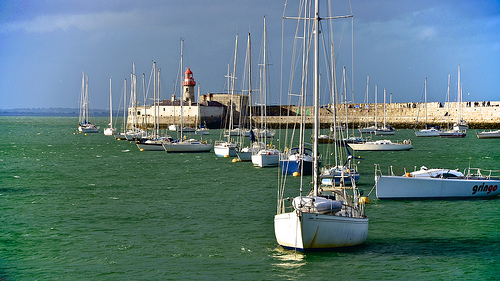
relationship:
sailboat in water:
[265, 2, 373, 246] [1, 115, 498, 280]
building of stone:
[151, 73, 247, 117] [132, 92, 245, 132]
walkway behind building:
[228, 96, 500, 127] [151, 73, 247, 117]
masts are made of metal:
[289, 1, 344, 199] [305, 2, 326, 203]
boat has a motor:
[349, 138, 413, 151] [403, 138, 411, 145]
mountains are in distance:
[2, 103, 136, 119] [4, 94, 130, 120]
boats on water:
[74, 69, 295, 182] [1, 115, 498, 280]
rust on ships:
[277, 237, 367, 249] [265, 2, 373, 246]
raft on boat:
[294, 194, 338, 215] [267, 5, 372, 243]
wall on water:
[241, 111, 500, 132] [1, 115, 498, 280]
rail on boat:
[277, 194, 306, 215] [267, 5, 372, 243]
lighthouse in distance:
[182, 68, 194, 85] [4, 94, 130, 120]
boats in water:
[74, 69, 295, 182] [1, 115, 498, 280]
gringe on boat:
[472, 182, 500, 196] [374, 162, 493, 197]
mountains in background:
[2, 103, 136, 119] [0, 14, 499, 139]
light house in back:
[179, 67, 203, 102] [134, 65, 495, 105]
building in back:
[151, 73, 247, 117] [134, 65, 495, 105]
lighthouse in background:
[182, 68, 194, 85] [0, 14, 499, 139]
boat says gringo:
[374, 162, 493, 197] [472, 182, 500, 196]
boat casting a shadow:
[267, 5, 372, 243] [311, 231, 494, 257]